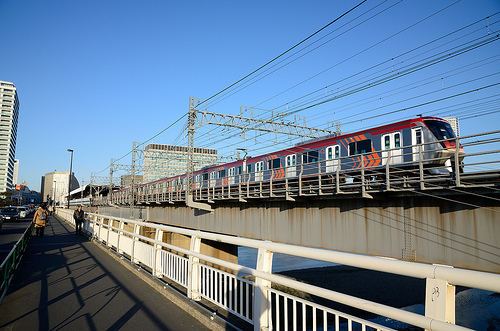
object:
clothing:
[73, 208, 84, 234]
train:
[112, 114, 465, 202]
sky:
[1, 0, 497, 179]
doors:
[380, 132, 392, 166]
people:
[32, 206, 48, 237]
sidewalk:
[1, 206, 209, 329]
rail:
[89, 131, 500, 206]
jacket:
[33, 207, 49, 228]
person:
[73, 206, 85, 235]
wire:
[94, 0, 498, 178]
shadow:
[2, 227, 75, 293]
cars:
[1, 207, 20, 223]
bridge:
[0, 209, 498, 330]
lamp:
[68, 149, 73, 210]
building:
[143, 143, 217, 186]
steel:
[185, 196, 212, 212]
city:
[1, 81, 218, 215]